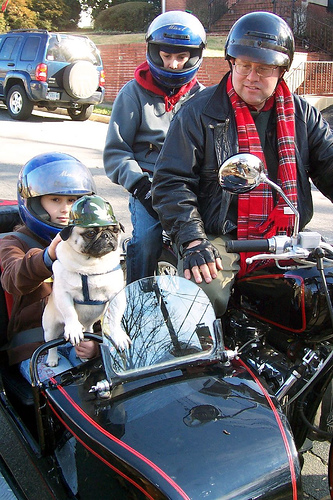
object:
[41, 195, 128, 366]
pug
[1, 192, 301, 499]
sidecar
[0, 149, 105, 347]
kid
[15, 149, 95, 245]
helmet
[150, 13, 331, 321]
man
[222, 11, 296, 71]
helmet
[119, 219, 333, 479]
motorcycle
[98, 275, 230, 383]
windshield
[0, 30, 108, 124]
suv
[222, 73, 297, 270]
scarf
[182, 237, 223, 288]
gloves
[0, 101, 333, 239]
road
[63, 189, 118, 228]
helmet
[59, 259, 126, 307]
harness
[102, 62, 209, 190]
sweater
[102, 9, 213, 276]
boy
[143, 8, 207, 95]
helmet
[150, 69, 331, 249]
jacket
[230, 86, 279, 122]
neck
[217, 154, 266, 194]
rearview mirror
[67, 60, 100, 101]
tire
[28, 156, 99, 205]
visor